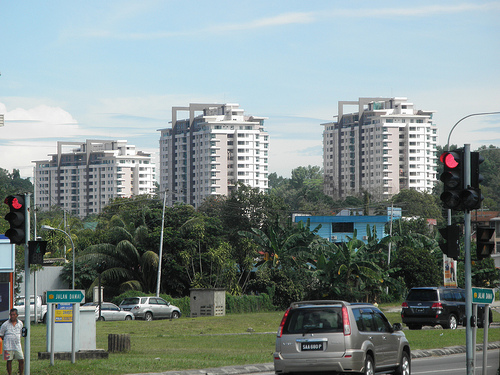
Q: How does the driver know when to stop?
A: Traffic light.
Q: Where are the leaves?
A: Trees.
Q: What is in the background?
A: Buildings.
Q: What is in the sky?
A: Clouds.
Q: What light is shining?
A: Red stoplight.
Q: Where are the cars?
A: Road.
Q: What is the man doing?
A: Standing.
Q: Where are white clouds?
A: In the sky.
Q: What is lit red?
A: Traffic light.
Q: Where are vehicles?
A: In the street.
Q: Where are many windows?
A: On the buildings.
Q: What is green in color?
A: Grass.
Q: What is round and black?
A: Tires.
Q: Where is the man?
A: On the left, by the pole for the traffic light.